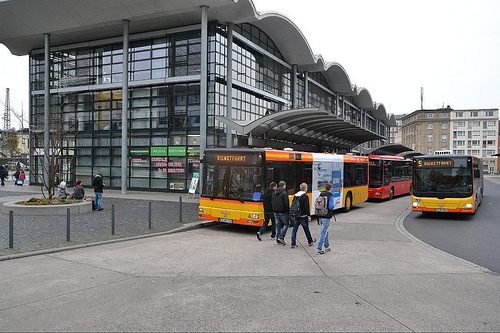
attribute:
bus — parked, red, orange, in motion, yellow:
[205, 129, 374, 211]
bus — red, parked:
[370, 145, 410, 195]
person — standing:
[313, 190, 340, 236]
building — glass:
[62, 44, 228, 185]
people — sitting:
[59, 179, 83, 197]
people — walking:
[261, 177, 344, 252]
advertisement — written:
[143, 147, 190, 190]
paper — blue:
[327, 162, 344, 192]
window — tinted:
[267, 162, 302, 188]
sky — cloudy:
[383, 13, 444, 70]